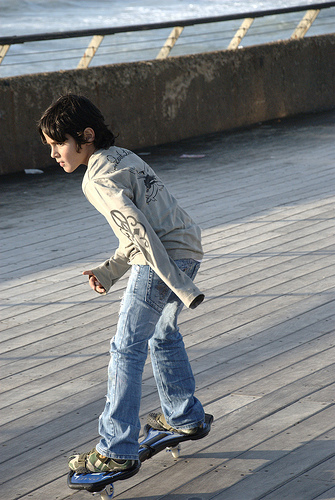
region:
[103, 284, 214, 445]
the jeans are blue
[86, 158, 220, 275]
the swaeter is grey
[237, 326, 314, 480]
the floor is made of wood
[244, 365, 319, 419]
the wood is grey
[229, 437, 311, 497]
shadow is on the floor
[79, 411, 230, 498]
the skateboard has two wheels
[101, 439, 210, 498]
the wheels are white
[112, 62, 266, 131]
the wall is brown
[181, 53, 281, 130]
the wall is made of concrete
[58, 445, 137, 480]
the shoes are brown and green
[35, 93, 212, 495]
a boy on a skateboard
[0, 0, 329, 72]
the surf behind the wall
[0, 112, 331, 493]
the wood the boy is skateboarding on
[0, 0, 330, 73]
the railing on the wall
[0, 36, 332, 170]
the concrete wall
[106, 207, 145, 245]
black design on the boy's sleeve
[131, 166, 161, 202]
the design on the back of the boy's shirt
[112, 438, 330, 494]
shadow behind the boy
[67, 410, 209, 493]
the skateboard the boy is riding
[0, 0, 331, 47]
black top of the railing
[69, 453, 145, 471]
left foot on boy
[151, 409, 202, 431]
right foot on boy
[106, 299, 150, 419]
left leg on boy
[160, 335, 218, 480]
right leg on boy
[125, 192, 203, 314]
left arm on boy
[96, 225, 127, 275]
right arm on boy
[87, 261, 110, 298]
right hand on boy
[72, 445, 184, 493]
left shoe on boy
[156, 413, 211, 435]
right shoe on boy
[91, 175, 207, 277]
tan shirt on boy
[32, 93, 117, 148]
Black hair on a boy.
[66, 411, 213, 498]
A blue and black skateboard with white wheels.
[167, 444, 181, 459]
White back wheel on a skateboard.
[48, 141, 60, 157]
The nose of a boy.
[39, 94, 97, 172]
The head of a boy with black hair.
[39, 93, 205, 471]
A boy in a grey sweatshirt with black hair.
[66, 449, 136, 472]
Shoe on a kid's left foot.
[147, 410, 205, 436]
Shoe on a boy's right foot.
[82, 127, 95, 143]
Left ear of a boy.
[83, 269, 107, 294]
Right hand fingers of a boy.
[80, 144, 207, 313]
a gray shirt on a boy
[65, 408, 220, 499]
a blue and black board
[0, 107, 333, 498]
a faded wooden boardwalk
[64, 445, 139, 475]
a green and gray shoe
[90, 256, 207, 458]
a pair of blue jeans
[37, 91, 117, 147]
dark hair on a boy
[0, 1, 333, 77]
a railing next to a boardwalk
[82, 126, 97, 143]
the ear of a boy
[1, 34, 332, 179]
a worn concrete wall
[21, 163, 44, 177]
a white paper on a boardwalk